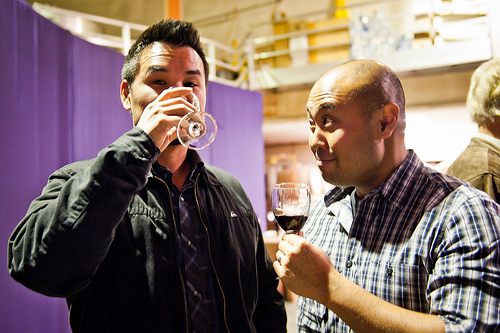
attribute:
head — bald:
[285, 52, 440, 174]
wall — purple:
[21, 46, 77, 124]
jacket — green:
[8, 137, 285, 329]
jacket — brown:
[438, 135, 499, 205]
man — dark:
[13, 14, 285, 331]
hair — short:
[117, 14, 220, 82]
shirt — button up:
[240, 150, 496, 310]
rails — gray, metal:
[247, 36, 362, 58]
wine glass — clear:
[269, 181, 311, 238]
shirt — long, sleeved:
[36, 151, 287, 312]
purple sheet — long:
[1, 0, 266, 331]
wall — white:
[415, 110, 457, 148]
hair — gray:
[464, 58, 499, 127]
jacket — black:
[47, 140, 287, 307]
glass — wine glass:
[271, 182, 308, 281]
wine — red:
[275, 214, 307, 233]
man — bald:
[270, 57, 498, 331]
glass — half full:
[265, 178, 312, 243]